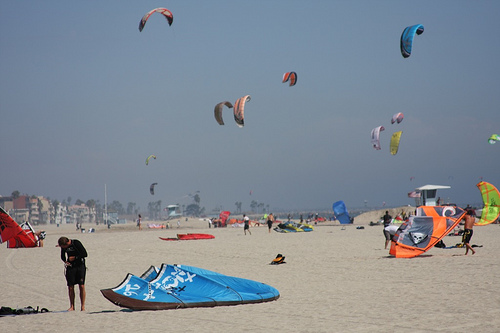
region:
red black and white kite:
[136, 4, 176, 34]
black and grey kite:
[210, 97, 234, 129]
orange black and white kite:
[232, 94, 250, 126]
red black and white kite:
[280, 70, 298, 87]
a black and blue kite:
[398, 23, 425, 60]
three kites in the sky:
[367, 110, 409, 156]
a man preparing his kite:
[0, 235, 287, 315]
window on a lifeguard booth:
[425, 188, 436, 200]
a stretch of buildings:
[1, 194, 136, 222]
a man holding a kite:
[395, 208, 481, 258]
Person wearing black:
[48, 229, 94, 309]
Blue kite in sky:
[389, 25, 434, 60]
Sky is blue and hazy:
[4, 10, 498, 192]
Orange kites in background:
[384, 183, 477, 264]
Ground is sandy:
[91, 238, 499, 330]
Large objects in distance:
[166, 187, 291, 227]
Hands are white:
[56, 255, 80, 267]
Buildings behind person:
[13, 190, 113, 224]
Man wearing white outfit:
[238, 210, 255, 236]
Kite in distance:
[141, 179, 163, 199]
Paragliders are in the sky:
[116, 5, 481, 165]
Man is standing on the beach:
[41, 215, 101, 320]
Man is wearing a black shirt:
[46, 225, 97, 295]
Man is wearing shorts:
[55, 260, 91, 300]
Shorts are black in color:
[56, 260, 91, 295]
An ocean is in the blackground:
[276, 196, 369, 233]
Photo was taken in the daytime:
[7, 6, 498, 331]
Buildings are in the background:
[11, 183, 116, 229]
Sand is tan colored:
[0, 232, 497, 331]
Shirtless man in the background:
[447, 202, 484, 271]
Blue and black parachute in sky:
[400, 21, 427, 55]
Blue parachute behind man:
[103, 256, 283, 306]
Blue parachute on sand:
[103, 260, 281, 307]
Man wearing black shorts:
[55, 234, 87, 312]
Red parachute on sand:
[154, 227, 217, 244]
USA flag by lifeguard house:
[407, 184, 422, 200]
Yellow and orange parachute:
[472, 179, 498, 230]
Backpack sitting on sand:
[268, 251, 287, 264]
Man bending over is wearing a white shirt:
[381, 222, 397, 249]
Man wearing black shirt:
[55, 234, 90, 311]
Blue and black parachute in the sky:
[390, 15, 426, 60]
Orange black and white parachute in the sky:
[280, 65, 300, 86]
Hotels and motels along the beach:
[10, 190, 123, 230]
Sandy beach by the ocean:
[302, 258, 479, 325]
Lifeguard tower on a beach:
[408, 172, 459, 212]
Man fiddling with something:
[55, 234, 97, 321]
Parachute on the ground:
[473, 177, 498, 229]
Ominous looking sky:
[42, 61, 188, 143]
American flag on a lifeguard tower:
[407, 186, 422, 207]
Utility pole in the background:
[100, 178, 109, 223]